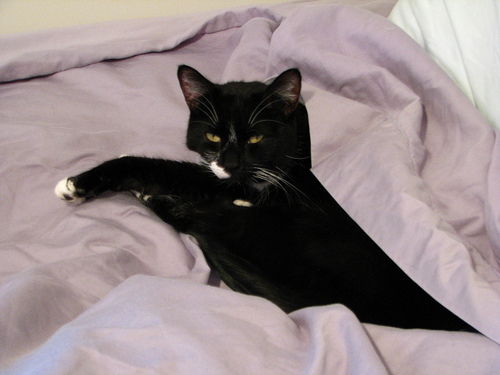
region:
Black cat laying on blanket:
[50, 48, 482, 349]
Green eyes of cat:
[200, 125, 271, 147]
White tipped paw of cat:
[53, 173, 83, 204]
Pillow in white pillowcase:
[375, 2, 499, 130]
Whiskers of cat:
[249, 162, 302, 199]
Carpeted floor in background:
[5, 1, 394, 33]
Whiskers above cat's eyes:
[190, 90, 287, 132]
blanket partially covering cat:
[34, 274, 499, 366]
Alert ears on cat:
[172, 60, 310, 110]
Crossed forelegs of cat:
[47, 156, 199, 206]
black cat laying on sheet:
[24, 17, 494, 371]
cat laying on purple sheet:
[22, 5, 497, 348]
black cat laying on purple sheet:
[32, 32, 454, 370]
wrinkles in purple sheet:
[344, 52, 475, 222]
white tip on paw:
[43, 159, 110, 214]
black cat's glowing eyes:
[197, 119, 282, 151]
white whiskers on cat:
[250, 155, 323, 220]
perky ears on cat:
[164, 53, 318, 110]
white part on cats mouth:
[205, 148, 249, 183]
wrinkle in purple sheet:
[35, 245, 191, 352]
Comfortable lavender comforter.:
[89, 225, 161, 342]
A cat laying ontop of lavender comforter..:
[111, 68, 499, 333]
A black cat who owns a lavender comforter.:
[25, 93, 470, 334]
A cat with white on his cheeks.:
[170, 58, 301, 198]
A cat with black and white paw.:
[13, 165, 130, 210]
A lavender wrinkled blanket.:
[31, 211, 169, 361]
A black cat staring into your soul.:
[175, 50, 300, 197]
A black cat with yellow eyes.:
[170, 95, 285, 161]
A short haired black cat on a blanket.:
[63, 83, 473, 343]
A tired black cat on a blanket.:
[48, 88, 470, 331]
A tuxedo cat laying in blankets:
[51, 64, 482, 331]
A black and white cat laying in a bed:
[53, 62, 482, 330]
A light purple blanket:
[0, 2, 497, 374]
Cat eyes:
[208, 131, 267, 142]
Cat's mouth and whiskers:
[184, 162, 314, 209]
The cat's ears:
[176, 63, 302, 113]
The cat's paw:
[54, 173, 104, 205]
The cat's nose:
[224, 160, 239, 171]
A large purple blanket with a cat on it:
[1, 3, 499, 374]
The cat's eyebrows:
[188, 94, 288, 127]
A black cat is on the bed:
[160, 63, 448, 330]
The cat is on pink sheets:
[72, 158, 361, 358]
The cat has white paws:
[42, 164, 130, 201]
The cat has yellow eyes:
[170, 100, 371, 215]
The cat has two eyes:
[142, 53, 345, 158]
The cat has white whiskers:
[191, 115, 301, 217]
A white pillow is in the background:
[352, 0, 498, 112]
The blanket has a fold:
[29, 37, 166, 110]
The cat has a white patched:
[206, 153, 269, 214]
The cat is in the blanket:
[164, 43, 434, 370]